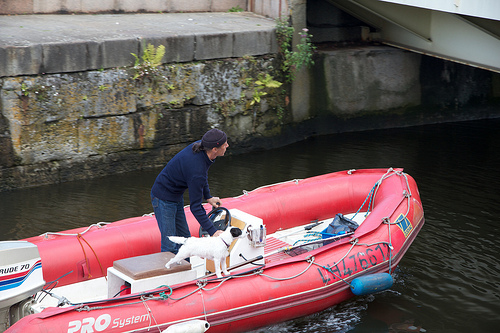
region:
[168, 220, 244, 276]
A dog on the boat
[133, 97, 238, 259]
A man drives the boat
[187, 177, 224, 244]
The man grabs his dog.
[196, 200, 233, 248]
The wheel on the boat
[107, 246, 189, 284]
A brown cushion for the seat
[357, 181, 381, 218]
A blue and white rope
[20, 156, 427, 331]
A red boat.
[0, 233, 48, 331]
The engine of a boat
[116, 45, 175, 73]
Weeds growing from wall.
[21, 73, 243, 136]
Mold on the brick wall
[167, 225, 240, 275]
A white dog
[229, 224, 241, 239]
The dog's ear is black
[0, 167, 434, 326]
A red boat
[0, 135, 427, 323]
A man and his dog riding a boat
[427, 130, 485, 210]
The water is calm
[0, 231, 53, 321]
The boat's motor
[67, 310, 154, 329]
The boat says "Pro System"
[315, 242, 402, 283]
The number on the boat is LH476612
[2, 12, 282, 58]
Cement platform above the water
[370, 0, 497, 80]
A bridge above the water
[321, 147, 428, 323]
the inflatable boat is red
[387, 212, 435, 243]
the sign is blue and white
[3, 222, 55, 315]
the motor is grey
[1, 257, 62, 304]
the sign is red blue black and white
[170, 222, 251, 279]
the dog is white and black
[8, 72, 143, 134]
the concrete has yellow brown moss on it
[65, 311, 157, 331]
the words are white in color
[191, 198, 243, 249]
the steering wheel is black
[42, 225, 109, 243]
the rope is white in color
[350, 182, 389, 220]
this rope is blue and white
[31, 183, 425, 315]
Life saving boat is red color.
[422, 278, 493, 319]
water is green color.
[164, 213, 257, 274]
Dog is standing in the boat.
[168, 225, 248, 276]
Dog is white and black color.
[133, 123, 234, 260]
One man is holding the steering.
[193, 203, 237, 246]
steering is black color.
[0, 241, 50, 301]
Motor is at the back of the boat.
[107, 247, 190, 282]
Cushion is brown color.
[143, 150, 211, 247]
Man is wearing blue dress.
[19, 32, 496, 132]
Tunnel is grey color.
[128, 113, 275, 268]
The man is driving the boat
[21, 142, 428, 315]
The boat is red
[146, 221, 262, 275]
White and black dog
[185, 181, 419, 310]
Brown ropes on side of boat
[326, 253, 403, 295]
Blue buoy on side of boat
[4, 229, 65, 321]
The engine is grey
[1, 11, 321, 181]
Grey brick on edge of water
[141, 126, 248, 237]
The man is wearing a blue sweater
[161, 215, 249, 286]
The dog is standing on the edge of the boat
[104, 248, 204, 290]
The boat has a brown and white seat